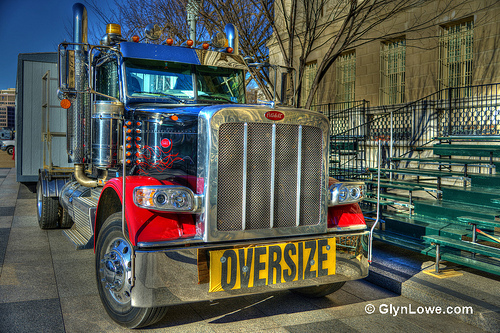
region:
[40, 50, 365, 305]
A truck is parked by the bleachers.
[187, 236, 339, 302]
A yellow sign with big letter in front of the truck.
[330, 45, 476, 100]
The buildings has window.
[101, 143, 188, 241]
The truck is red.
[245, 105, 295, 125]
The truck has a red logo on it.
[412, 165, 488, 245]
The bleachers is green.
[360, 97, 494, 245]
The bleachers is in front of the building.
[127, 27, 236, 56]
The lights on top of the truck.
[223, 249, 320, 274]
The sign has black writing.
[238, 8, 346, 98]
The tree is bare.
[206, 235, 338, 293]
The yellow sign on the front of the diesel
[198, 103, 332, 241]
The over sized grill in front of the truck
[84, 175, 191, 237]
The red cover to the tire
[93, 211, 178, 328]
The tire to the diesel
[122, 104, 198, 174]
The black hood of the diesel had red designs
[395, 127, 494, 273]
A seating of green benches and steps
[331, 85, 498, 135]
The color of the railing is black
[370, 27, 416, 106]
A large window to a tall building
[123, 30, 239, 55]
The lights on top of the truck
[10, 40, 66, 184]
The load on the back of the diesel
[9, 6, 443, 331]
large truck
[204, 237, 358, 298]
black and yellow sign on the bumper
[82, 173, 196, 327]
red paint above the wheel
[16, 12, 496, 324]
truck parked next to bleachers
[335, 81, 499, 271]
a set of bleachers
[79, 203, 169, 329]
large front wheel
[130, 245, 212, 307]
reflection in the silver bumper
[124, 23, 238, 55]
row of small orange lights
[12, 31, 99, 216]
white and gray trailer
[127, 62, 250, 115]
windshield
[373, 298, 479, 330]
Name of site that provides the picture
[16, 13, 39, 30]
A clear blue sky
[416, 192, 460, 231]
Small section of green bleachers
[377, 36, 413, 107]
One of the windows of the building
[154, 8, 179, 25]
Few brown branches on the tree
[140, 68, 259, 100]
Front window of the truck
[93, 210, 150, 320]
Front right wheel of the truck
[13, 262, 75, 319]
Gray and black tiled sidewalk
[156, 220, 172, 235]
Red part of the truck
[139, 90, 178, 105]
Right windshield wiper of truck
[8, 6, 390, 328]
a very large truck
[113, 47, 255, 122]
the front windshield of a truck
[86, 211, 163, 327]
the front tire of a truck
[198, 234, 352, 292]
a yellow and black oversize sign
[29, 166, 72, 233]
the rear tire on the cab of a truck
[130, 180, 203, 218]
the headlight on a truck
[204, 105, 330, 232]
the grill of a truck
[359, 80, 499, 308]
green and silver bleachers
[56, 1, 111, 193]
the muffler on a truck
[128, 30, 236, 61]
the caution lights on a truck